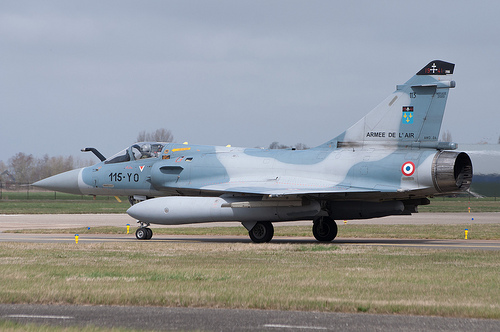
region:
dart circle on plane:
[399, 161, 416, 176]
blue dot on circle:
[404, 165, 412, 173]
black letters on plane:
[364, 130, 416, 141]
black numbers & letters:
[106, 172, 141, 184]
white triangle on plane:
[138, 162, 146, 173]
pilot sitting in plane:
[138, 143, 160, 160]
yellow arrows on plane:
[403, 110, 415, 122]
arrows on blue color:
[401, 109, 415, 124]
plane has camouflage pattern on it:
[29, 57, 479, 247]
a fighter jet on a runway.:
[29, 50, 476, 241]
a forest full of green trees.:
[5, 145, 79, 185]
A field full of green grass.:
[0, 221, 497, 305]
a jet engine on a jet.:
[427, 140, 477, 192]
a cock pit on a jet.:
[85, 122, 182, 179]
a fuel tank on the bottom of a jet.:
[122, 187, 345, 229]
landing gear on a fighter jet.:
[308, 211, 345, 247]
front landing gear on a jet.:
[131, 218, 156, 246]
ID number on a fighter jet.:
[105, 159, 148, 187]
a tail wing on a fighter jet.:
[311, 54, 461, 150]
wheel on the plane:
[244, 222, 279, 244]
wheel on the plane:
[311, 213, 338, 245]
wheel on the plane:
[129, 223, 155, 240]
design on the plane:
[398, 161, 420, 180]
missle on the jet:
[128, 199, 321, 226]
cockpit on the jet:
[107, 139, 163, 163]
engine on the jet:
[435, 152, 472, 189]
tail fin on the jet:
[323, 57, 456, 147]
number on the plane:
[105, 164, 142, 188]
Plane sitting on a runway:
[2, 57, 491, 253]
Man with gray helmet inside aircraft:
[26, 60, 474, 245]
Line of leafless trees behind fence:
[6, 127, 499, 202]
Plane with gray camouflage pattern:
[36, 56, 473, 243]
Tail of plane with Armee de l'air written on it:
[325, 59, 460, 150]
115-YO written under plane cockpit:
[27, 59, 472, 247]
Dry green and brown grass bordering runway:
[0, 197, 499, 329]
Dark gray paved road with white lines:
[1, 297, 498, 329]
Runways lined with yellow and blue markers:
[0, 209, 496, 247]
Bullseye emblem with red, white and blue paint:
[398, 159, 417, 176]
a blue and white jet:
[26, 56, 466, 256]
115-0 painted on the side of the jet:
[108, 169, 145, 185]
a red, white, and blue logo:
[399, 156, 416, 178]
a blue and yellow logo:
[398, 102, 420, 124]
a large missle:
[123, 182, 328, 231]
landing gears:
[243, 213, 338, 244]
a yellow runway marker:
[69, 230, 89, 256]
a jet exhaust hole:
[433, 143, 478, 197]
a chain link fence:
[8, 168, 113, 205]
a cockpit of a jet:
[101, 130, 181, 161]